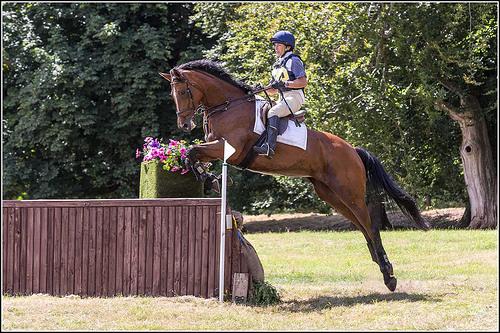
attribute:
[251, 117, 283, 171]
boots — black , leather, riding boots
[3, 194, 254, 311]
fence — brown , wood , barrier fence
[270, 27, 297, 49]
helmet — blue , plastic riding helmet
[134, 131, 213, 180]
flowers — pink, purple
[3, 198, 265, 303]
fence — wooden equestrian fence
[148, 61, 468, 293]
horse — brown , black 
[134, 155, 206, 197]
basket — green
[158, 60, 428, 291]
horse — moving quickly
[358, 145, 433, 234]
tail — black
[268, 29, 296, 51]
helmet — blue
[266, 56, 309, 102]
shirt — blue, yellow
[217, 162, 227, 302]
flag pole — white, metal , mini flag pole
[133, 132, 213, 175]
flowers — colorful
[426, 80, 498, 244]
trunk — brown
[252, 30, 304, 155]
rider — equestrian rider, in competition 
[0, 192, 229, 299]
fence — wooden , on somebody's property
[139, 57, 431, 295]
horses — jumping over something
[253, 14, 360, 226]
rider — horseback rider